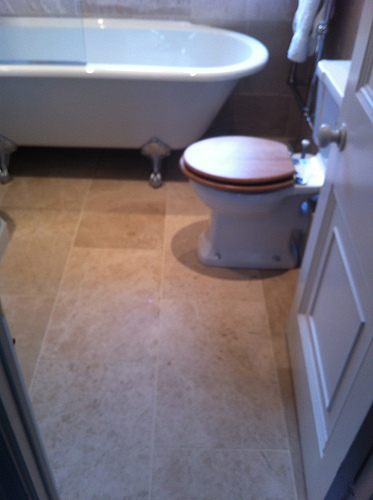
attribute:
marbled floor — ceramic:
[2, 157, 305, 497]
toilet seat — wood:
[175, 133, 307, 265]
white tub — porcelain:
[1, 12, 267, 187]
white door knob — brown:
[311, 119, 350, 151]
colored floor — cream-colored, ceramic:
[1, 163, 311, 494]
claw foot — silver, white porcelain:
[136, 133, 178, 186]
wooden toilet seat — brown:
[167, 134, 300, 190]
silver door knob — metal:
[306, 117, 351, 156]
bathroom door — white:
[278, 1, 371, 499]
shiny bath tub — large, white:
[1, 16, 269, 181]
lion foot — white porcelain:
[137, 137, 167, 186]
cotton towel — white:
[288, 0, 329, 66]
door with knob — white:
[286, 1, 371, 499]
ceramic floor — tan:
[2, 173, 301, 498]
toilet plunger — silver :
[300, 133, 316, 156]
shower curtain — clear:
[2, 0, 197, 74]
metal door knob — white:
[312, 119, 353, 152]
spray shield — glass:
[1, 3, 86, 73]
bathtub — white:
[1, 17, 271, 148]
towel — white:
[286, 0, 335, 62]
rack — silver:
[284, 1, 338, 126]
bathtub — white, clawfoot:
[2, 17, 270, 192]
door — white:
[286, 3, 371, 497]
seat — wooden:
[180, 129, 312, 197]